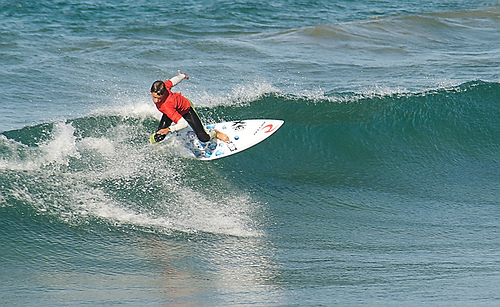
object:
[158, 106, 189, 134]
arm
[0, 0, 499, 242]
wave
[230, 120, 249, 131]
sticker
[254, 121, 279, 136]
logo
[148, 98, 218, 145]
wetsuit pants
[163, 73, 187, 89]
sleeve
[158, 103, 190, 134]
sleeve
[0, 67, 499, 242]
spray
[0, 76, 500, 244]
swell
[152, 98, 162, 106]
nose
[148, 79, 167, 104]
head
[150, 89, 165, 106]
face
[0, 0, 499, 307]
ocean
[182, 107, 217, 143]
leg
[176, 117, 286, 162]
surfboard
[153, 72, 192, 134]
tee shirt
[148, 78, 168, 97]
hair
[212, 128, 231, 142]
foot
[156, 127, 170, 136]
left hand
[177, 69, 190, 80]
right hand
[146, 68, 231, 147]
boy